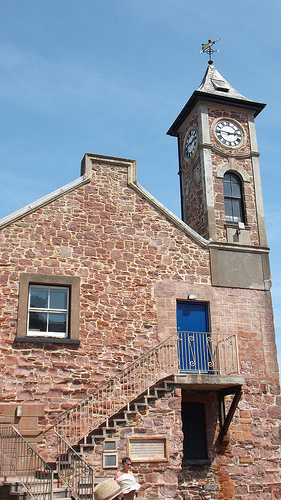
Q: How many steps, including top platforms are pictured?
A: Fifteen.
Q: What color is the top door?
A: Blue.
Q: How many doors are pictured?
A: Two.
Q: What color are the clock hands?
A: Black.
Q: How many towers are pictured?
A: One.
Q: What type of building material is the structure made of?
A: Stone.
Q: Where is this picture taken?
A: In front of a clock tower.